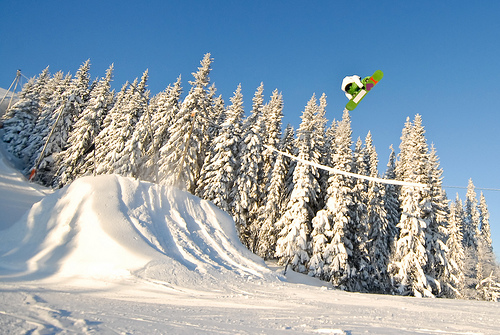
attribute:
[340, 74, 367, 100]
person — snowboarder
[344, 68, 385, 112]
snowboard — green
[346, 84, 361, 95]
helmet — green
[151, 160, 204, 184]
snow — bright, white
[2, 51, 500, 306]
trees — skinny, tall, evergreens, pine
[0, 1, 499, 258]
sky — clear, blue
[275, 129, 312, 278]
tree — pine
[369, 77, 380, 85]
letter — red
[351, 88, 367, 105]
space — white